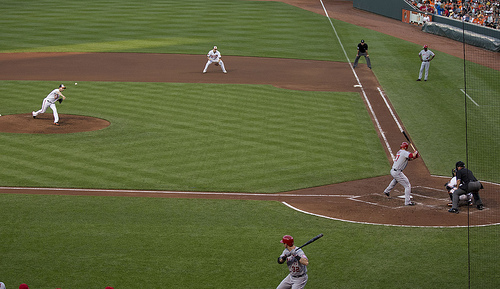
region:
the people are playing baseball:
[42, 15, 467, 282]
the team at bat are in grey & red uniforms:
[247, 222, 334, 287]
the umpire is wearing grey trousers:
[437, 147, 490, 217]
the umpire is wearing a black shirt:
[453, 147, 488, 212]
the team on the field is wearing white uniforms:
[173, 15, 233, 82]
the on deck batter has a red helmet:
[266, 227, 314, 247]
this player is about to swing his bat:
[373, 117, 433, 233]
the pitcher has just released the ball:
[21, 73, 93, 128]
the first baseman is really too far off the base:
[193, 31, 277, 86]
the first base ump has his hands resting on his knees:
[345, 31, 392, 76]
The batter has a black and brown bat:
[376, 115, 413, 210]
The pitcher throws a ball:
[33, 68, 98, 150]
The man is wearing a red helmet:
[265, 219, 322, 267]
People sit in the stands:
[373, 1, 494, 57]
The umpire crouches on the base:
[446, 148, 486, 216]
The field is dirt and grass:
[35, 19, 471, 265]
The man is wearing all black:
[348, 27, 378, 81]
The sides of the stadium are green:
[366, 5, 491, 52]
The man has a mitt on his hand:
[191, 37, 239, 92]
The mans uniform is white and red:
[258, 227, 309, 285]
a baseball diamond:
[0, 0, 496, 228]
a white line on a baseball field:
[2, 175, 343, 196]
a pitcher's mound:
[1, 101, 111, 136]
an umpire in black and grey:
[455, 155, 485, 210]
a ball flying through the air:
[70, 77, 76, 82]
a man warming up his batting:
[265, 217, 332, 283]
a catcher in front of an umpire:
[441, 160, 461, 203]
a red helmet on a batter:
[397, 138, 410, 152]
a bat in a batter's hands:
[399, 126, 424, 157]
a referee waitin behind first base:
[343, 35, 373, 69]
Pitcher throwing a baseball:
[41, 81, 68, 128]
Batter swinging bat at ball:
[391, 131, 418, 206]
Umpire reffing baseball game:
[453, 158, 483, 215]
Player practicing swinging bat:
[276, 233, 315, 286]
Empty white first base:
[352, 82, 365, 89]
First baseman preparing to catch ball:
[201, 45, 228, 77]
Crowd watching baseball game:
[424, 2, 496, 24]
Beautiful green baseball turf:
[157, 116, 294, 151]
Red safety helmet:
[280, 235, 296, 245]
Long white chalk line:
[206, 186, 340, 203]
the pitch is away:
[27, 68, 91, 130]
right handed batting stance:
[379, 125, 429, 213]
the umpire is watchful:
[439, 147, 490, 227]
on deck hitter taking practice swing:
[259, 214, 349, 284]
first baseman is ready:
[192, 35, 249, 94]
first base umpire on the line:
[341, 32, 427, 214]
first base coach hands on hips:
[406, 35, 453, 96]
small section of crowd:
[413, 2, 499, 30]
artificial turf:
[110, 78, 372, 225]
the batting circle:
[279, 137, 498, 234]